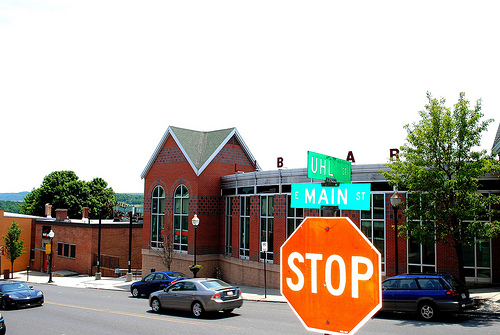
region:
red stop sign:
[269, 208, 389, 333]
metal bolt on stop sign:
[321, 223, 334, 235]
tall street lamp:
[187, 208, 205, 283]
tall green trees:
[22, 165, 119, 220]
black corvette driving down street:
[2, 277, 47, 315]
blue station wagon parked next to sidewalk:
[379, 265, 475, 323]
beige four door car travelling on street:
[134, 275, 254, 320]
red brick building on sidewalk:
[0, 202, 140, 282]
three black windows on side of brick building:
[54, 238, 81, 260]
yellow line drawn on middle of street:
[50, 297, 270, 334]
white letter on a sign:
[345, 255, 378, 300]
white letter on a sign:
[316, 249, 348, 300]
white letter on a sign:
[301, 250, 323, 297]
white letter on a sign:
[284, 249, 303, 294]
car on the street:
[144, 275, 251, 323]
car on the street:
[0, 273, 48, 310]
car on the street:
[122, 267, 187, 301]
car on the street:
[372, 266, 476, 321]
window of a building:
[232, 191, 257, 266]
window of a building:
[170, 182, 193, 256]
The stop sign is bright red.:
[278, 215, 383, 334]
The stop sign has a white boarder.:
[278, 215, 383, 334]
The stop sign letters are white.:
[286, 248, 376, 299]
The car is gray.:
[148, 275, 245, 319]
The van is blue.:
[378, 272, 470, 319]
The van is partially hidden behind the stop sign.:
[381, 270, 471, 319]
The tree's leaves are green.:
[383, 90, 499, 244]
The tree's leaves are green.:
[20, 168, 117, 216]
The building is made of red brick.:
[138, 124, 498, 290]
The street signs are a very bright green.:
[289, 147, 373, 211]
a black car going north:
[2, 275, 44, 305]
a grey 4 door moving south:
[143, 276, 242, 317]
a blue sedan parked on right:
[127, 268, 179, 294]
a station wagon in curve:
[385, 273, 476, 319]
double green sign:
[287, 148, 376, 213]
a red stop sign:
[274, 217, 394, 333]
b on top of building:
[274, 152, 288, 172]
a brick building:
[135, 123, 498, 295]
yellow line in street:
[44, 298, 324, 331]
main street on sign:
[287, 180, 376, 212]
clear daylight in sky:
[0, 22, 499, 184]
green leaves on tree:
[394, 92, 494, 289]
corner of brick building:
[42, 226, 140, 274]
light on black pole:
[191, 213, 201, 279]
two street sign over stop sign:
[280, 151, 382, 334]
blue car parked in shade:
[382, 268, 486, 324]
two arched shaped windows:
[149, 180, 190, 252]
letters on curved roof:
[232, 148, 413, 185]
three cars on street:
[2, 268, 246, 318]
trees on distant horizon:
[2, 189, 139, 211]